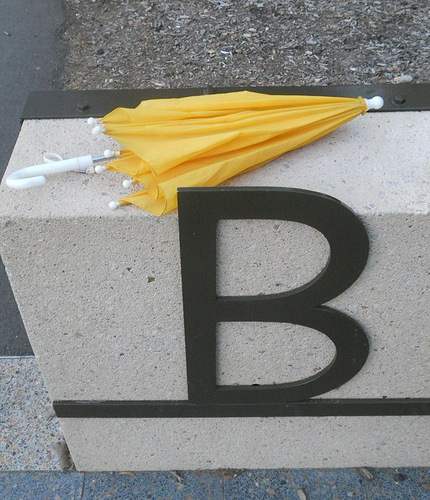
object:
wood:
[169, 468, 197, 482]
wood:
[213, 47, 230, 55]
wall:
[0, 213, 430, 470]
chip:
[370, 64, 388, 76]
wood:
[114, 471, 137, 477]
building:
[0, 83, 430, 471]